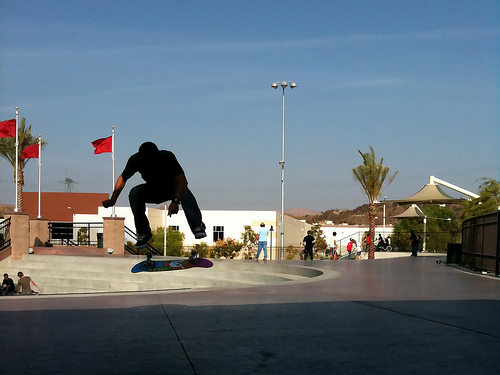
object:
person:
[0, 272, 15, 295]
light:
[290, 82, 297, 90]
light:
[282, 81, 289, 88]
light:
[271, 83, 279, 89]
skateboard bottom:
[132, 258, 211, 271]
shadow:
[0, 297, 500, 375]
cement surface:
[0, 254, 500, 375]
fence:
[0, 213, 163, 259]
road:
[0, 254, 500, 347]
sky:
[0, 0, 498, 171]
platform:
[0, 249, 500, 353]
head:
[138, 141, 159, 156]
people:
[14, 271, 40, 299]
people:
[302, 229, 317, 260]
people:
[328, 231, 338, 259]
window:
[213, 225, 225, 244]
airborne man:
[101, 140, 207, 248]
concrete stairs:
[3, 252, 339, 299]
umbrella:
[391, 182, 467, 205]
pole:
[429, 174, 480, 199]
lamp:
[271, 79, 299, 261]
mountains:
[282, 198, 477, 225]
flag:
[91, 135, 113, 155]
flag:
[20, 144, 40, 159]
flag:
[0, 118, 17, 137]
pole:
[110, 124, 117, 217]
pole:
[36, 131, 43, 218]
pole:
[14, 105, 19, 214]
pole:
[279, 86, 285, 261]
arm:
[172, 159, 190, 206]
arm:
[109, 153, 139, 200]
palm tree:
[351, 146, 399, 260]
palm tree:
[1, 118, 46, 213]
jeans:
[255, 241, 268, 258]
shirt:
[257, 228, 269, 243]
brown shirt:
[17, 277, 32, 293]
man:
[256, 221, 269, 264]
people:
[408, 220, 422, 257]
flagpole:
[34, 134, 42, 220]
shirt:
[18, 275, 32, 290]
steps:
[0, 252, 337, 300]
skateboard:
[131, 257, 214, 274]